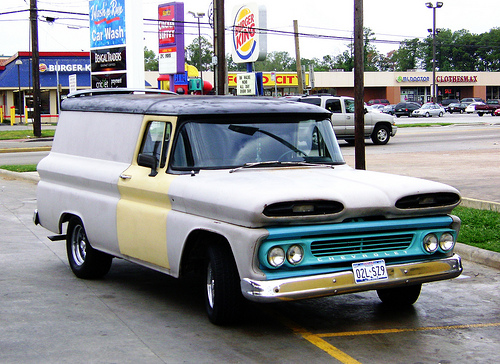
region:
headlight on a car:
[267, 245, 284, 269]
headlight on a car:
[283, 243, 302, 264]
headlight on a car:
[420, 231, 437, 253]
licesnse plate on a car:
[350, 257, 388, 283]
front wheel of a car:
[198, 240, 238, 326]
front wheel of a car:
[378, 281, 420, 305]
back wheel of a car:
[68, 215, 112, 277]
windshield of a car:
[168, 118, 345, 170]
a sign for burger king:
[227, 4, 267, 65]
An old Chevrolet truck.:
[33, 88, 460, 328]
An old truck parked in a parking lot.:
[1, 87, 498, 362]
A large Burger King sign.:
[226, 0, 267, 97]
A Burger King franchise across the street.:
[0, 50, 149, 125]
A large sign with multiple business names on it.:
[87, 1, 142, 91]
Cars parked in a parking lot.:
[371, 95, 498, 124]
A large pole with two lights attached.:
[424, 0, 444, 114]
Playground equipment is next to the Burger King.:
[0, 49, 212, 124]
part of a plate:
[343, 263, 389, 286]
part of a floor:
[139, 313, 166, 356]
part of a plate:
[343, 268, 388, 293]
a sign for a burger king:
[220, 7, 270, 70]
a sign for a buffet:
[143, 3, 203, 72]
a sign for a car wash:
[69, 13, 131, 47]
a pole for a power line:
[325, 15, 388, 184]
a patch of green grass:
[386, 190, 491, 259]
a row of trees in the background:
[124, 44, 491, 94]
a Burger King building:
[2, 45, 149, 127]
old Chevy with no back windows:
[5, 5, 495, 351]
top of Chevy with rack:
[51, 85, 331, 120]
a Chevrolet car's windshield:
[180, 111, 345, 171]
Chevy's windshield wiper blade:
[225, 155, 336, 175]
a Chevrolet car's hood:
[169, 159, 466, 230]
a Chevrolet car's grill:
[247, 213, 465, 275]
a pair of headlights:
[261, 240, 308, 270]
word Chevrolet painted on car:
[313, 246, 414, 263]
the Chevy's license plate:
[348, 255, 393, 286]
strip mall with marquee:
[7, 3, 497, 125]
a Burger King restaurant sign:
[228, 1, 265, 62]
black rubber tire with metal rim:
[202, 250, 242, 325]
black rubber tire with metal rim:
[65, 219, 114, 279]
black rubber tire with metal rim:
[379, 284, 422, 306]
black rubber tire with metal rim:
[372, 122, 392, 142]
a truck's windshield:
[170, 119, 347, 164]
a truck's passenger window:
[136, 119, 169, 166]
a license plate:
[350, 258, 387, 281]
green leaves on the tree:
[466, 46, 492, 66]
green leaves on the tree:
[340, 52, 352, 62]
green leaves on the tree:
[326, 52, 346, 72]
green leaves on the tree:
[301, 52, 324, 72]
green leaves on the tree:
[284, 50, 299, 70]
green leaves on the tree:
[268, 48, 297, 67]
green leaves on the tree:
[187, 35, 209, 57]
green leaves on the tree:
[396, 42, 422, 71]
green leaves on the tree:
[436, 40, 451, 55]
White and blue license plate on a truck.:
[350, 258, 387, 285]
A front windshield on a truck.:
[171, 113, 346, 173]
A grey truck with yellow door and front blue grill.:
[31, 85, 461, 327]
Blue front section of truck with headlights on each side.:
[252, 215, 457, 279]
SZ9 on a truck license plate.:
[370, 265, 385, 278]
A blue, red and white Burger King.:
[0, 50, 151, 122]